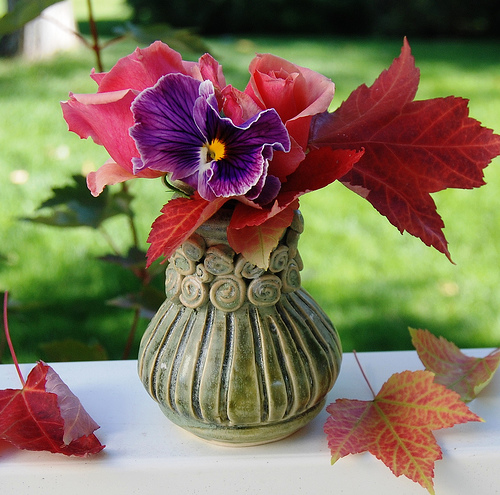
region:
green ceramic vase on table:
[138, 224, 344, 440]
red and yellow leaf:
[328, 343, 478, 494]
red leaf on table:
[2, 290, 107, 458]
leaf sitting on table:
[406, 325, 498, 400]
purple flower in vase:
[128, 73, 290, 202]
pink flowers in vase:
[58, 40, 326, 189]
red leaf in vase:
[321, 44, 498, 261]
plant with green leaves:
[2, 2, 172, 363]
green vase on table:
[140, 188, 340, 443]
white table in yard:
[0, 345, 496, 492]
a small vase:
[162, 279, 317, 429]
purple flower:
[141, 96, 192, 152]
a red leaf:
[16, 383, 93, 448]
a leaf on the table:
[359, 400, 441, 457]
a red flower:
[76, 83, 118, 137]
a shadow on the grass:
[341, 283, 420, 343]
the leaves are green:
[26, 175, 97, 227]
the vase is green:
[173, 297, 321, 399]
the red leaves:
[377, 104, 460, 186]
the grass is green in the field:
[330, 217, 381, 267]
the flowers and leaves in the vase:
[60, 35, 499, 270]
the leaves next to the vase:
[1, 289, 498, 494]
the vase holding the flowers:
[137, 190, 343, 446]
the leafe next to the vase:
[325, 348, 486, 494]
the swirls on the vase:
[162, 236, 303, 312]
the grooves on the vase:
[136, 296, 343, 430]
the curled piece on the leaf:
[34, 354, 102, 445]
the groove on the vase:
[247, 307, 274, 423]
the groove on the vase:
[265, 305, 295, 419]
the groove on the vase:
[167, 309, 199, 417]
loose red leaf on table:
[0, 290, 121, 486]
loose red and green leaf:
[319, 338, 466, 493]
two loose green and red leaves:
[322, 320, 487, 482]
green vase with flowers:
[62, 5, 373, 494]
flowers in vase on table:
[65, 22, 387, 482]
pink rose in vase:
[220, 40, 344, 240]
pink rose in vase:
[46, 37, 201, 194]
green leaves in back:
[32, 172, 155, 342]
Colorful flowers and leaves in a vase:
[55, 25, 495, 449]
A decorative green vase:
[132, 204, 346, 451]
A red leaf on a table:
[0, 283, 111, 465]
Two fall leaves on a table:
[318, 321, 496, 493]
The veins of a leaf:
[320, 366, 483, 493]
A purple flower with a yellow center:
[123, 68, 296, 211]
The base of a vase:
[150, 399, 332, 454]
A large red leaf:
[307, 29, 499, 269]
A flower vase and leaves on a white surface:
[3, 31, 494, 493]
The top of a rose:
[243, 47, 339, 124]